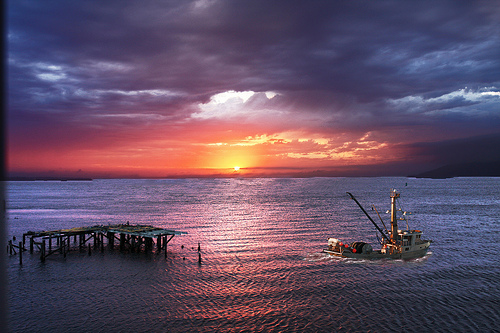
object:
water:
[235, 195, 300, 245]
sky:
[7, 5, 497, 174]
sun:
[233, 165, 240, 171]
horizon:
[2, 174, 499, 179]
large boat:
[306, 166, 446, 274]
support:
[26, 233, 168, 252]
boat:
[312, 185, 437, 262]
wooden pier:
[18, 222, 187, 274]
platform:
[25, 221, 188, 265]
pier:
[9, 218, 184, 275]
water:
[9, 177, 499, 331]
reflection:
[144, 175, 354, 329]